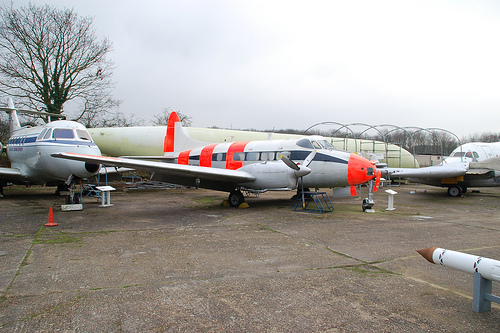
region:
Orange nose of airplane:
[344, 150, 378, 192]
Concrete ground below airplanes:
[128, 243, 355, 321]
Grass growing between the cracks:
[28, 228, 106, 253]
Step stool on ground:
[95, 182, 123, 209]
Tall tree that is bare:
[3, 13, 102, 103]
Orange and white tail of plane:
[156, 106, 186, 152]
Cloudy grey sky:
[181, 20, 380, 79]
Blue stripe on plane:
[3, 129, 85, 150]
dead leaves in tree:
[88, 59, 113, 81]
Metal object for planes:
[313, 116, 469, 155]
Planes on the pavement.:
[37, 125, 472, 207]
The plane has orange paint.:
[347, 145, 381, 195]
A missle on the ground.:
[405, 231, 495, 302]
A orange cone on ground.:
[32, 197, 64, 232]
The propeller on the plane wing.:
[278, 160, 319, 195]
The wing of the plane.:
[56, 131, 246, 205]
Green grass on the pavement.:
[27, 223, 94, 255]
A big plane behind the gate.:
[92, 115, 444, 170]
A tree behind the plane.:
[13, 8, 111, 161]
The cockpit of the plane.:
[31, 122, 118, 149]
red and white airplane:
[50, 108, 385, 224]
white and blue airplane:
[0, 98, 110, 204]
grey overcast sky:
[110, 5, 485, 120]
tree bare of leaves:
[2, 3, 124, 123]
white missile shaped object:
[412, 238, 499, 286]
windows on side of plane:
[205, 150, 292, 162]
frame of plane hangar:
[297, 115, 463, 181]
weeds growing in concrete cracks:
[10, 228, 112, 270]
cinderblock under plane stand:
[59, 198, 83, 215]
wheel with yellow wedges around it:
[220, 188, 249, 211]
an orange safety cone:
[42, 203, 60, 232]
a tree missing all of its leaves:
[0, 1, 122, 108]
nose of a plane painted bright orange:
[345, 147, 385, 202]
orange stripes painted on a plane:
[155, 108, 267, 198]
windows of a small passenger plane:
[212, 150, 292, 167]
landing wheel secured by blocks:
[218, 184, 250, 211]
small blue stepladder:
[282, 183, 340, 220]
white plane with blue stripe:
[0, 100, 107, 189]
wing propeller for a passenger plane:
[275, 143, 320, 216]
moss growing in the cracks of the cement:
[9, 225, 169, 258]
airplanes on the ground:
[21, 36, 497, 310]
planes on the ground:
[17, 40, 495, 304]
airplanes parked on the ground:
[22, 47, 477, 323]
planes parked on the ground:
[14, 56, 499, 304]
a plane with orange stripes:
[128, 58, 456, 282]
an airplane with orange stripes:
[127, 90, 391, 228]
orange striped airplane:
[127, 91, 452, 254]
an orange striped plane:
[134, 108, 404, 240]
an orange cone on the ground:
[34, 191, 94, 266]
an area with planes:
[16, 30, 496, 301]